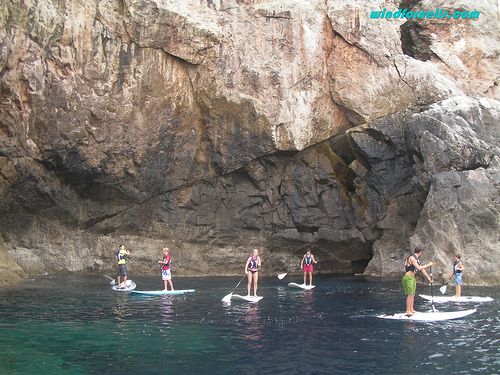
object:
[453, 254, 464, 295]
person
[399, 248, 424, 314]
person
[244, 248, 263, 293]
person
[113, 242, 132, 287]
person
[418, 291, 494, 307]
paddle board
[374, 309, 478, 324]
paddle board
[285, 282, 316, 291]
paddle board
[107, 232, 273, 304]
people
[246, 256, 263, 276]
swimsuit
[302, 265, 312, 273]
shorts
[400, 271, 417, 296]
shorts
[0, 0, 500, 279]
cliff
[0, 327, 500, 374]
water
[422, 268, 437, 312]
paddle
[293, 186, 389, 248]
rock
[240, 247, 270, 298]
girl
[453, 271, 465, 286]
shorts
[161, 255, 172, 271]
shirt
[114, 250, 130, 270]
shirt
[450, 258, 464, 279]
jacket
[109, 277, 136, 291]
paddle board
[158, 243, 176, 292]
person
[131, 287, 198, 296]
paddle board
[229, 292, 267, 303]
paddle board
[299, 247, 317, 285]
person